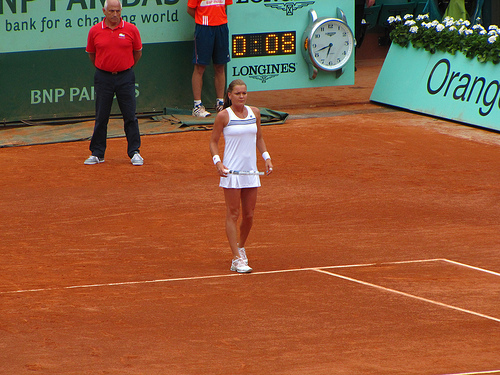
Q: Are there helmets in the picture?
A: No, there are no helmets.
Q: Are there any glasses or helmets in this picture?
A: No, there are no helmets or glasses.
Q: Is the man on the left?
A: Yes, the man is on the left of the image.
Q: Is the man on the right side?
A: No, the man is on the left of the image.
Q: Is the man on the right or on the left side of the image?
A: The man is on the left of the image.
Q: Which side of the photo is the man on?
A: The man is on the left of the image.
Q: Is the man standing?
A: Yes, the man is standing.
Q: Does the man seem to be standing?
A: Yes, the man is standing.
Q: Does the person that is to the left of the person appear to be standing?
A: Yes, the man is standing.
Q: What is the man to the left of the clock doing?
A: The man is standing.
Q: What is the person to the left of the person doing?
A: The man is standing.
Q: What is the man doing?
A: The man is standing.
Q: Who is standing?
A: The man is standing.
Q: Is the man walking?
A: No, the man is standing.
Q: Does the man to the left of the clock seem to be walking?
A: No, the man is standing.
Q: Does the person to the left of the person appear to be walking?
A: No, the man is standing.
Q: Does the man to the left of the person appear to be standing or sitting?
A: The man is standing.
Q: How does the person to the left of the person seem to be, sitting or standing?
A: The man is standing.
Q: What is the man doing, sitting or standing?
A: The man is standing.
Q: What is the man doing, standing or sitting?
A: The man is standing.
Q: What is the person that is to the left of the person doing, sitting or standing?
A: The man is standing.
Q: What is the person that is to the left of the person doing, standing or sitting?
A: The man is standing.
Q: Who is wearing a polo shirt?
A: The man is wearing a polo shirt.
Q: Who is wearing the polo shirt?
A: The man is wearing a polo shirt.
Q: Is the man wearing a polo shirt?
A: Yes, the man is wearing a polo shirt.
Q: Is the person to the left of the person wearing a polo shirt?
A: Yes, the man is wearing a polo shirt.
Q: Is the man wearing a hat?
A: No, the man is wearing a polo shirt.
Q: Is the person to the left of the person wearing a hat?
A: No, the man is wearing a polo shirt.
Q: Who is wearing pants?
A: The man is wearing pants.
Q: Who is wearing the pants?
A: The man is wearing pants.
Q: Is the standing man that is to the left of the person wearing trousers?
A: Yes, the man is wearing trousers.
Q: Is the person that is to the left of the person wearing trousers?
A: Yes, the man is wearing trousers.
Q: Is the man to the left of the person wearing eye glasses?
A: No, the man is wearing trousers.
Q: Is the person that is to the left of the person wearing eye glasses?
A: No, the man is wearing trousers.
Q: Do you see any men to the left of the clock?
A: Yes, there is a man to the left of the clock.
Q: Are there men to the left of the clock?
A: Yes, there is a man to the left of the clock.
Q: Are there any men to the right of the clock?
A: No, the man is to the left of the clock.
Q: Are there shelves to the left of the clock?
A: No, there is a man to the left of the clock.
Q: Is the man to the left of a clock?
A: Yes, the man is to the left of a clock.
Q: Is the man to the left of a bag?
A: No, the man is to the left of a clock.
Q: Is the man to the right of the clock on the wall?
A: No, the man is to the left of the clock.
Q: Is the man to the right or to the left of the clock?
A: The man is to the left of the clock.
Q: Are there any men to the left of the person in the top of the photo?
A: Yes, there is a man to the left of the person.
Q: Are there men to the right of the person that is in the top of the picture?
A: No, the man is to the left of the person.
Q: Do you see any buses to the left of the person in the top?
A: No, there is a man to the left of the person.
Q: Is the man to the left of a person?
A: Yes, the man is to the left of a person.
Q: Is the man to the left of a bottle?
A: No, the man is to the left of a person.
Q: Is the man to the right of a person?
A: No, the man is to the left of a person.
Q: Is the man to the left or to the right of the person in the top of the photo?
A: The man is to the left of the person.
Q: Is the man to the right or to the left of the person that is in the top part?
A: The man is to the left of the person.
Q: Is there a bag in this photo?
A: No, there are no bags.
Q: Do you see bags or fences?
A: No, there are no bags or fences.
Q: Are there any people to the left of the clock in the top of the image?
A: Yes, there is a person to the left of the clock.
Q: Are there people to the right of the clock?
A: No, the person is to the left of the clock.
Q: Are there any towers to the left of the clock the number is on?
A: No, there is a person to the left of the clock.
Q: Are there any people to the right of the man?
A: Yes, there is a person to the right of the man.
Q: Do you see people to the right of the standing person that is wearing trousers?
A: Yes, there is a person to the right of the man.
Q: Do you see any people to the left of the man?
A: No, the person is to the right of the man.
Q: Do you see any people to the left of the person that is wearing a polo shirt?
A: No, the person is to the right of the man.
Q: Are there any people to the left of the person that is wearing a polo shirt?
A: No, the person is to the right of the man.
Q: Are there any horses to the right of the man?
A: No, there is a person to the right of the man.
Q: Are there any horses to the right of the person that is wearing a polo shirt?
A: No, there is a person to the right of the man.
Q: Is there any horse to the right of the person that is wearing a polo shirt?
A: No, there is a person to the right of the man.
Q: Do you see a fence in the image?
A: No, there are no fences.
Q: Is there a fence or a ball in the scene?
A: No, there are no fences or balls.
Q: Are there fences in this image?
A: No, there are no fences.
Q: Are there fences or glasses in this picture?
A: No, there are no fences or glasses.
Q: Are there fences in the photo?
A: No, there are no fences.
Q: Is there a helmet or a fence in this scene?
A: No, there are no fences or helmets.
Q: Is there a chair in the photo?
A: No, there are no chairs.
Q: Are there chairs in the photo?
A: No, there are no chairs.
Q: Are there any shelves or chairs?
A: No, there are no chairs or shelves.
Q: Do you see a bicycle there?
A: No, there are no bicycles.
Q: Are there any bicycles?
A: No, there are no bicycles.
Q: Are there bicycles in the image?
A: No, there are no bicycles.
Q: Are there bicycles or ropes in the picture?
A: No, there are no bicycles or ropes.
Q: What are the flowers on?
A: The flowers are on the wall.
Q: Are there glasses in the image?
A: No, there are no glasses.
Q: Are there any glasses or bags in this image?
A: No, there are no glasses or bags.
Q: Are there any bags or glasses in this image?
A: No, there are no glasses or bags.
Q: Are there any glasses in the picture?
A: No, there are no glasses.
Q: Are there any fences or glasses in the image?
A: No, there are no glasses or fences.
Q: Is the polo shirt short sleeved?
A: Yes, the polo shirt is short sleeved.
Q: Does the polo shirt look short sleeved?
A: Yes, the polo shirt is short sleeved.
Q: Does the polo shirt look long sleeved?
A: No, the polo shirt is short sleeved.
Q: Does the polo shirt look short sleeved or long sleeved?
A: The polo shirt is short sleeved.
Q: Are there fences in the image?
A: No, there are no fences.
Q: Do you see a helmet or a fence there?
A: No, there are no fences or helmets.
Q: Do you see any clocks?
A: Yes, there is a clock.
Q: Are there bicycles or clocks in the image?
A: Yes, there is a clock.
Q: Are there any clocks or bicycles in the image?
A: Yes, there is a clock.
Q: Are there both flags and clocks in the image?
A: No, there is a clock but no flags.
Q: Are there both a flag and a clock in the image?
A: No, there is a clock but no flags.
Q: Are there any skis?
A: No, there are no skis.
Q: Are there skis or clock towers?
A: No, there are no skis or clock towers.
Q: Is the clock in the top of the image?
A: Yes, the clock is in the top of the image.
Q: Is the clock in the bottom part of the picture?
A: No, the clock is in the top of the image.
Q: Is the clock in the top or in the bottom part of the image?
A: The clock is in the top of the image.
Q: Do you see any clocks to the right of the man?
A: Yes, there is a clock to the right of the man.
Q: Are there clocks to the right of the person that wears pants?
A: Yes, there is a clock to the right of the man.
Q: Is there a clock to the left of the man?
A: No, the clock is to the right of the man.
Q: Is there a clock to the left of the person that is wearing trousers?
A: No, the clock is to the right of the man.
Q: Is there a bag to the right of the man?
A: No, there is a clock to the right of the man.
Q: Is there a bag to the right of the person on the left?
A: No, there is a clock to the right of the man.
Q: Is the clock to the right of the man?
A: Yes, the clock is to the right of the man.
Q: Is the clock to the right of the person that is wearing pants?
A: Yes, the clock is to the right of the man.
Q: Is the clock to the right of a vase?
A: No, the clock is to the right of the man.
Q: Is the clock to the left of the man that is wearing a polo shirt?
A: No, the clock is to the right of the man.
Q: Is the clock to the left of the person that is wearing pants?
A: No, the clock is to the right of the man.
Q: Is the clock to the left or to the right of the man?
A: The clock is to the right of the man.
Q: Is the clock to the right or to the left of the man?
A: The clock is to the right of the man.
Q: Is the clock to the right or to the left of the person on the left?
A: The clock is to the right of the man.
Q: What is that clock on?
A: The clock is on the wall.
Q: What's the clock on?
A: The clock is on the wall.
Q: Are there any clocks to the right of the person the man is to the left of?
A: Yes, there is a clock to the right of the person.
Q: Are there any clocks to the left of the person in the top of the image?
A: No, the clock is to the right of the person.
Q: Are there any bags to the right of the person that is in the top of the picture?
A: No, there is a clock to the right of the person.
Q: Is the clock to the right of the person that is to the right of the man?
A: Yes, the clock is to the right of the person.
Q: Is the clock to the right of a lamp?
A: No, the clock is to the right of the person.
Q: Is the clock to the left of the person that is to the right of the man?
A: No, the clock is to the right of the person.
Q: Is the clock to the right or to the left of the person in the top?
A: The clock is to the right of the person.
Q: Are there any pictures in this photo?
A: No, there are no pictures.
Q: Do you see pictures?
A: No, there are no pictures.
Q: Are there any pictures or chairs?
A: No, there are no pictures or chairs.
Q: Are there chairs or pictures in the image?
A: No, there are no pictures or chairs.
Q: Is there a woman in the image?
A: Yes, there is a woman.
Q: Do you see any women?
A: Yes, there is a woman.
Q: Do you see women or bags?
A: Yes, there is a woman.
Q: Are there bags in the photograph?
A: No, there are no bags.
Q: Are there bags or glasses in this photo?
A: No, there are no bags or glasses.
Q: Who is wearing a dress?
A: The woman is wearing a dress.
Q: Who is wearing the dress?
A: The woman is wearing a dress.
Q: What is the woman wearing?
A: The woman is wearing a dress.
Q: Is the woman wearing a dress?
A: Yes, the woman is wearing a dress.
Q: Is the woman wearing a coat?
A: No, the woman is wearing a dress.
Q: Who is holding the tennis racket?
A: The woman is holding the tennis racket.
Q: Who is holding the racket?
A: The woman is holding the tennis racket.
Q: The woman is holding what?
A: The woman is holding the tennis racket.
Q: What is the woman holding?
A: The woman is holding the tennis racket.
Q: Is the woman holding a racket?
A: Yes, the woman is holding a racket.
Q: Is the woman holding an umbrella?
A: No, the woman is holding a racket.